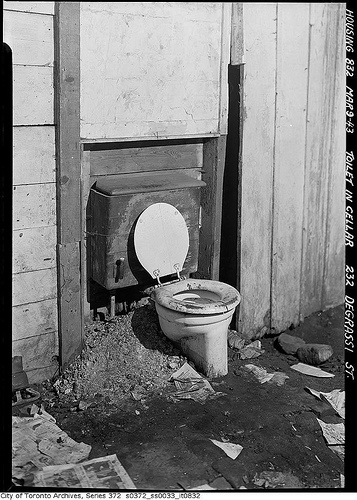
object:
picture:
[0, 0, 345, 488]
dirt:
[46, 304, 215, 405]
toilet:
[91, 164, 241, 379]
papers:
[199, 428, 247, 460]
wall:
[237, 8, 342, 338]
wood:
[240, 4, 342, 174]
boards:
[0, 9, 59, 66]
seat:
[144, 277, 242, 318]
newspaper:
[1, 405, 140, 491]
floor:
[0, 390, 352, 499]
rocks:
[51, 305, 191, 400]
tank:
[85, 177, 211, 292]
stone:
[276, 326, 309, 357]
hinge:
[149, 264, 188, 291]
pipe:
[104, 288, 116, 321]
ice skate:
[11, 350, 42, 406]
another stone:
[277, 330, 306, 354]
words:
[345, 9, 353, 373]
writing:
[5, 491, 208, 498]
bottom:
[10, 479, 353, 497]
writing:
[339, 0, 354, 391]